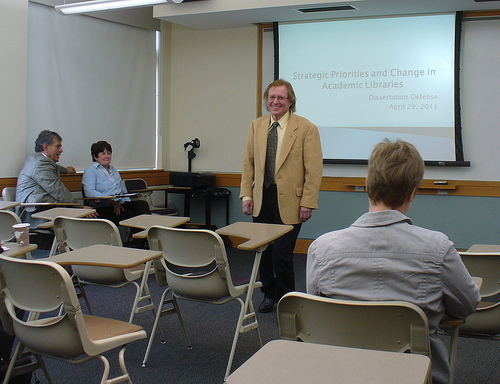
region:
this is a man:
[220, 50, 322, 301]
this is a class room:
[9, 8, 493, 380]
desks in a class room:
[2, 160, 493, 377]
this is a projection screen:
[254, 3, 499, 190]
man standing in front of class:
[50, 14, 487, 261]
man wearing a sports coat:
[228, 88, 328, 220]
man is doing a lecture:
[228, 60, 328, 245]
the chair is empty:
[148, 183, 274, 347]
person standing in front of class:
[231, 68, 327, 315]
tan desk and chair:
[1, 235, 168, 381]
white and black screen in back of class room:
[266, 10, 484, 174]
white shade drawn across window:
[18, 1, 168, 184]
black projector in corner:
[160, 130, 235, 232]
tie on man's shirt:
[263, 119, 283, 191]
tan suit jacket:
[235, 111, 325, 228]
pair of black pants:
[247, 190, 308, 309]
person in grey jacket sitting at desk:
[271, 135, 497, 382]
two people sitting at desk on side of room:
[0, 114, 167, 236]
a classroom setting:
[0, 0, 498, 380]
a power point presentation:
[272, 15, 469, 168]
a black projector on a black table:
[168, 169, 215, 188]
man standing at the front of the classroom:
[237, 79, 322, 308]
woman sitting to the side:
[80, 140, 148, 219]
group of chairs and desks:
[0, 180, 498, 379]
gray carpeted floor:
[28, 252, 495, 382]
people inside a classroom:
[16, 80, 482, 382]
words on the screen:
[293, 66, 442, 114]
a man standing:
[234, 80, 325, 308]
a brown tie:
[263, 121, 279, 218]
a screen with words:
[271, 5, 463, 170]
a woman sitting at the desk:
[84, 135, 152, 227]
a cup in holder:
[11, 219, 31, 246]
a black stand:
[160, 179, 234, 254]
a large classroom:
[1, 0, 494, 380]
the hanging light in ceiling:
[44, 0, 181, 17]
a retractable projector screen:
[269, 13, 470, 168]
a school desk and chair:
[140, 221, 292, 376]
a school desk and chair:
[0, 242, 159, 382]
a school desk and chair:
[52, 211, 188, 346]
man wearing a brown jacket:
[231, 110, 320, 210]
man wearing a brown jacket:
[286, 204, 481, 324]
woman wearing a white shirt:
[79, 153, 128, 203]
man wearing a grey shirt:
[17, 150, 69, 203]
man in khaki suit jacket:
[233, 75, 329, 317]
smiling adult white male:
[260, 77, 297, 119]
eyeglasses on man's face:
[261, 91, 291, 106]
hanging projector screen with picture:
[267, 7, 472, 179]